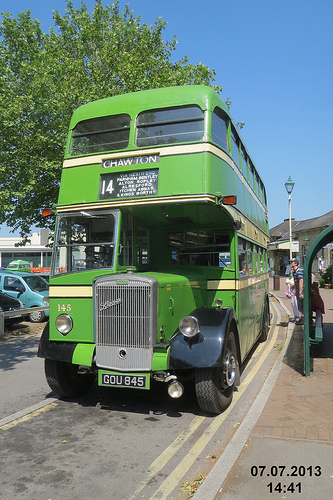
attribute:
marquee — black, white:
[99, 160, 159, 196]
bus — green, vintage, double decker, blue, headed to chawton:
[67, 89, 270, 385]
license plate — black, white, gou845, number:
[101, 374, 146, 387]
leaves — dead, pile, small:
[183, 469, 202, 499]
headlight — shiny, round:
[185, 316, 203, 337]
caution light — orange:
[225, 196, 240, 208]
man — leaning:
[284, 255, 310, 324]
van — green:
[2, 258, 33, 274]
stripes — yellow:
[198, 282, 271, 291]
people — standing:
[281, 260, 329, 324]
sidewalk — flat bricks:
[287, 278, 332, 421]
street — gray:
[18, 309, 259, 499]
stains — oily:
[18, 396, 89, 482]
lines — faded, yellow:
[158, 412, 214, 499]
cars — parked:
[0, 265, 40, 322]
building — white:
[13, 237, 85, 269]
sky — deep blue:
[157, 9, 332, 212]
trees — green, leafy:
[16, 20, 223, 268]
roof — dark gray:
[280, 212, 332, 231]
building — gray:
[275, 234, 327, 277]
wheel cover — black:
[176, 313, 228, 365]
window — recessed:
[160, 229, 239, 264]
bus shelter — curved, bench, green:
[306, 239, 331, 371]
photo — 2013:
[6, 14, 326, 499]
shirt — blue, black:
[286, 271, 305, 289]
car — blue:
[0, 296, 25, 312]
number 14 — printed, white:
[99, 174, 117, 197]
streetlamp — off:
[281, 174, 296, 195]